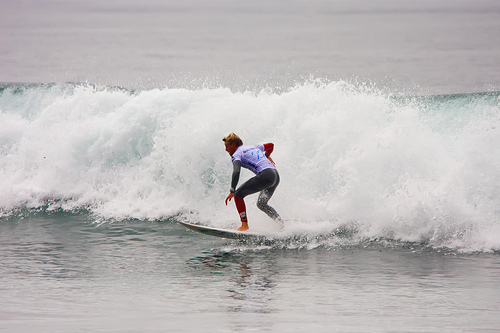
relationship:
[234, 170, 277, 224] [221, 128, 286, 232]
leg of person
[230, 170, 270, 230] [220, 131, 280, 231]
leg of person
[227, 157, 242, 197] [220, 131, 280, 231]
arm of surfing person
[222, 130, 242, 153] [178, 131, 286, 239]
head of surfing male surfer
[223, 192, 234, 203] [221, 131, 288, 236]
hand of surfer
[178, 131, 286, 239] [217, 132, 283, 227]
male surfer of surfer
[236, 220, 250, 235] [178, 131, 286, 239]
foot of male surfer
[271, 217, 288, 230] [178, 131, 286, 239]
foot of male surfer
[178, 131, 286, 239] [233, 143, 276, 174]
male surfer wearing shirt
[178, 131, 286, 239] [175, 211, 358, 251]
male surfer on surfboard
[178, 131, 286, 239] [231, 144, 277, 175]
male surfer has t shirt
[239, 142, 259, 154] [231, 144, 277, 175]
number on t shirt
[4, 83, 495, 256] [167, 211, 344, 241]
foam near surfboard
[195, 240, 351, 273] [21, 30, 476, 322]
waves in water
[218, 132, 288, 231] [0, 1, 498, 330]
male surfer in ocean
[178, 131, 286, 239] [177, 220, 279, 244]
male surfer on surfboard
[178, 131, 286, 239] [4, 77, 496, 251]
male surfer on wave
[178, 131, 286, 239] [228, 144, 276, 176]
male surfer wearing t shirt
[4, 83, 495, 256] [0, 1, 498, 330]
foam in ocean